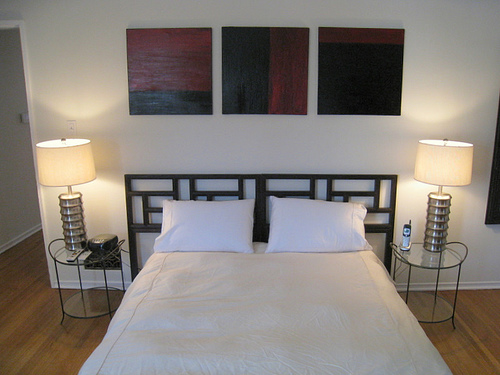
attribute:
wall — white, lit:
[1, 1, 498, 293]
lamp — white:
[416, 138, 475, 186]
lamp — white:
[34, 135, 98, 187]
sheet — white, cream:
[78, 242, 454, 372]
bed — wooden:
[80, 172, 454, 373]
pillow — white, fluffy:
[153, 200, 255, 254]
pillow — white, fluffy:
[266, 193, 371, 253]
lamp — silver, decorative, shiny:
[36, 137, 99, 250]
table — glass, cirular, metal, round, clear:
[47, 238, 126, 324]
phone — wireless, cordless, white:
[404, 220, 412, 248]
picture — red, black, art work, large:
[126, 27, 211, 116]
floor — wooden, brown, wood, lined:
[1, 228, 497, 374]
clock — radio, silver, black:
[88, 232, 119, 253]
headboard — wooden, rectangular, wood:
[123, 173, 401, 282]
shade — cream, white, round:
[35, 137, 98, 187]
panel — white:
[21, 113, 30, 125]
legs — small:
[52, 260, 126, 325]